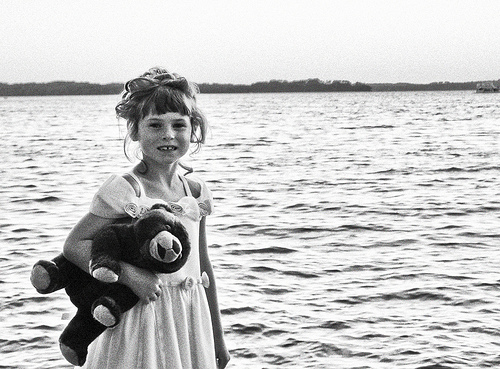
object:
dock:
[475, 79, 498, 94]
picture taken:
[0, 0, 499, 369]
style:
[113, 64, 208, 175]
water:
[0, 87, 499, 368]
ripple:
[394, 349, 420, 355]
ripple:
[204, 241, 302, 255]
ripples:
[1, 94, 108, 368]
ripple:
[339, 124, 394, 129]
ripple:
[433, 165, 500, 173]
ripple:
[434, 224, 460, 230]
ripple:
[327, 285, 454, 310]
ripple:
[299, 320, 351, 331]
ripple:
[287, 178, 362, 192]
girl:
[62, 65, 233, 368]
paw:
[90, 297, 123, 328]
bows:
[183, 270, 210, 290]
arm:
[61, 172, 139, 282]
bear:
[29, 202, 191, 367]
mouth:
[154, 241, 167, 260]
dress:
[90, 171, 223, 368]